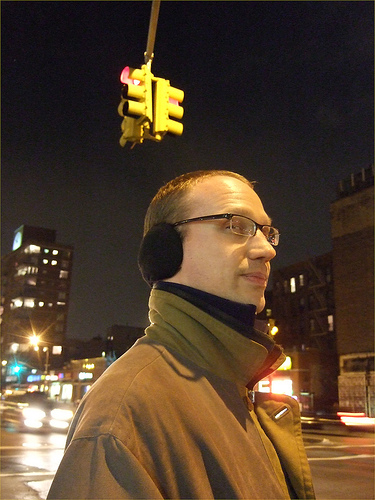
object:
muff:
[139, 223, 184, 281]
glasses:
[169, 213, 281, 245]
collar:
[145, 280, 267, 385]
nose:
[249, 230, 275, 261]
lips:
[241, 267, 268, 286]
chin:
[243, 292, 270, 311]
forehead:
[193, 179, 271, 220]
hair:
[144, 171, 253, 236]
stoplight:
[118, 64, 184, 148]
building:
[1, 224, 72, 368]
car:
[21, 405, 46, 428]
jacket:
[46, 281, 314, 498]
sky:
[3, 6, 374, 335]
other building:
[329, 162, 373, 416]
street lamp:
[39, 343, 51, 355]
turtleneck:
[155, 281, 257, 335]